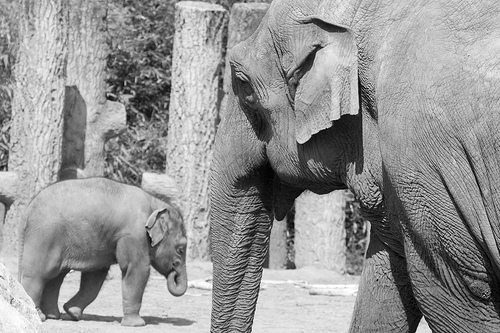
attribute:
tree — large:
[159, 9, 215, 266]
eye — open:
[235, 75, 254, 96]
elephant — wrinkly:
[175, 26, 433, 270]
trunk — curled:
[159, 257, 190, 299]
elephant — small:
[25, 181, 192, 321]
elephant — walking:
[209, 0, 498, 330]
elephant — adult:
[206, 31, 498, 302]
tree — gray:
[136, 17, 233, 324]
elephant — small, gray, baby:
[16, 170, 193, 320]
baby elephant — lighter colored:
[12, 172, 191, 332]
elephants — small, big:
[6, 180, 184, 321]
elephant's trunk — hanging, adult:
[202, 102, 272, 331]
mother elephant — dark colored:
[208, 3, 498, 331]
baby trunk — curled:
[164, 261, 191, 296]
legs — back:
[17, 219, 75, 317]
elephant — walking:
[15, 173, 200, 329]